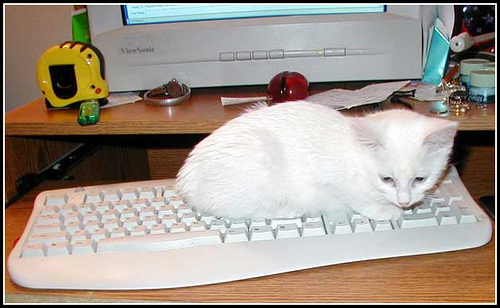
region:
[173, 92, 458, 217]
a small white cat.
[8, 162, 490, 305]
A computer keyboard with a cat on it.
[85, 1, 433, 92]
A computer monitor.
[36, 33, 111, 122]
A toy next to a computer.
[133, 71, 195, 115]
A metal object on a desk.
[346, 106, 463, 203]
A small white cat's head.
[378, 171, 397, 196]
the right eye of a cat.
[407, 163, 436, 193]
the left eye of a cat.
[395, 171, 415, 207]
a nose on the face of a cat.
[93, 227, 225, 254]
the space bar of a keyboard.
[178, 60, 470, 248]
the kitten is white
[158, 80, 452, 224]
the kitten is sitting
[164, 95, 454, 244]
the kitten on the keyboard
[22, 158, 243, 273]
the keyboard is white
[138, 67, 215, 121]
the watch on the desk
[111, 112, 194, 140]
the desk is tan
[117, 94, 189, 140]
the desk is made of wood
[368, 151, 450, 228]
the kitten has whiskers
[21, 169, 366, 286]
keyboard on the desk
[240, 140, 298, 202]
stomach of a cat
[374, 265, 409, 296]
part of a table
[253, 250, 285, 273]
edge of a keyboard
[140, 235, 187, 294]
part of a keyboard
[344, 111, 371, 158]
part of an ear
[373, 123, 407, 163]
head of a cat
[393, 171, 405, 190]
nose of a cat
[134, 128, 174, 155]
edge of a table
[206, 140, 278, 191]
part of a stomach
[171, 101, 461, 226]
White cat lying on white computer keyboard.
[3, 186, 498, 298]
A white computer keyboard.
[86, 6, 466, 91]
Bottom half of computer sitting on desk.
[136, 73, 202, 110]
Sliver watch sitting on desk.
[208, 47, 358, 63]
Control knobs on front of computer.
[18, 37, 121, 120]
Yellow pencil sharpener sitting on desk.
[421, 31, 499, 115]
Assorted paraphernalia sitting on desk.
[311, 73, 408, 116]
Papers lying on computer desk.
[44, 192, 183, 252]
Keys on computer keyboard.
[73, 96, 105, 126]
Cigarette lighter lying on desk.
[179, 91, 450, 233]
white cat on the keyboard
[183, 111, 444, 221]
cat lying on a keyboard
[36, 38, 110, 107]
tape measure on computer stand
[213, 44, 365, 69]
buttons at the bottom of the monitor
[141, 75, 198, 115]
wristwatch in front of monitor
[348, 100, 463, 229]
kitten lying on keyboards head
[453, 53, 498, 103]
three small jars to the right of the monitor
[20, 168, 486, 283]
white keyboard on computer stand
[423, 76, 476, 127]
jewelery behind kittens head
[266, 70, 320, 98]
red mouse in front of keyboard